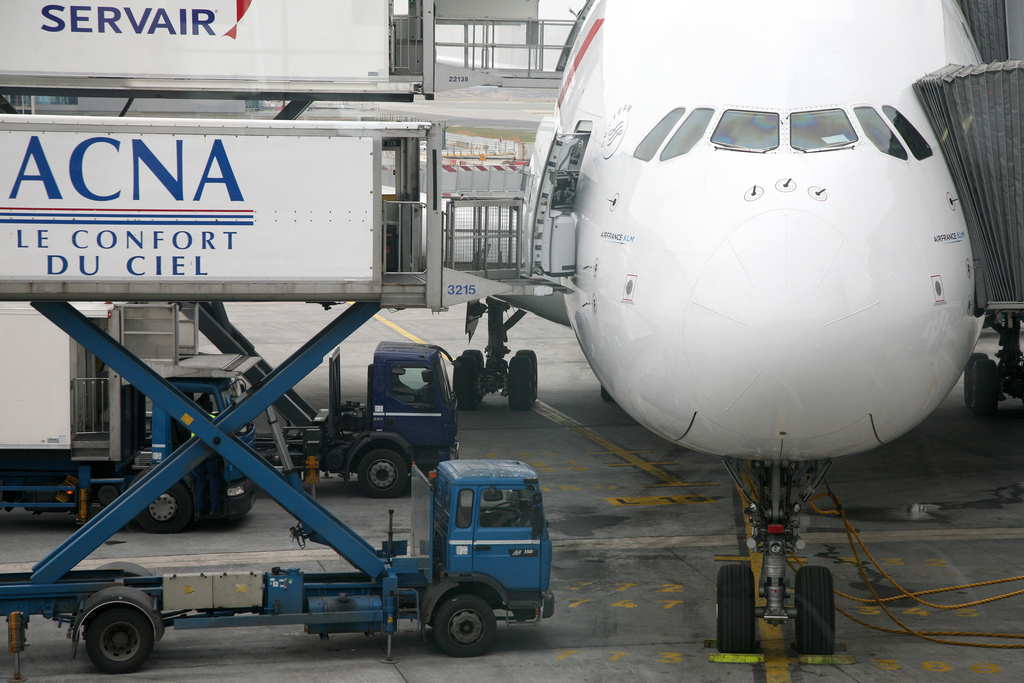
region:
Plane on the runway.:
[451, 51, 996, 618]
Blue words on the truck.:
[6, 111, 319, 293]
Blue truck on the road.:
[288, 441, 807, 638]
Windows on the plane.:
[615, 56, 971, 306]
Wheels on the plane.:
[688, 473, 905, 673]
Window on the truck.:
[452, 465, 555, 580]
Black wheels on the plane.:
[625, 444, 981, 647]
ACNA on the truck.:
[3, 125, 327, 252]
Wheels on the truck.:
[81, 548, 231, 678]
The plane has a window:
[714, 105, 781, 156]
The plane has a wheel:
[795, 566, 840, 661]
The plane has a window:
[847, 105, 931, 160]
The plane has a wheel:
[716, 557, 756, 656]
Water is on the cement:
[568, 522, 932, 656]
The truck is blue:
[19, 451, 548, 642]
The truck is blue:
[144, 342, 457, 507]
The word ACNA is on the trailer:
[6, 136, 253, 207]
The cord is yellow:
[821, 478, 1008, 644]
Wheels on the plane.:
[667, 529, 781, 657]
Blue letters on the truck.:
[27, 121, 291, 276]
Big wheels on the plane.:
[427, 302, 592, 427]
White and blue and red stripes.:
[550, 26, 643, 113]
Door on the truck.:
[417, 479, 522, 615]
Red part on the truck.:
[205, 10, 301, 71]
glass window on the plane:
[629, 108, 684, 159]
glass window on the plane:
[646, 100, 717, 159]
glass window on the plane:
[706, 103, 779, 154]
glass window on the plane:
[782, 100, 856, 154]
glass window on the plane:
[848, 104, 912, 163]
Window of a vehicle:
[479, 481, 534, 532]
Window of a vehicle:
[392, 363, 438, 406]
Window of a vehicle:
[386, 364, 434, 402]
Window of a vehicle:
[455, 489, 474, 528]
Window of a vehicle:
[480, 486, 532, 529]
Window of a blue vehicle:
[479, 483, 530, 531]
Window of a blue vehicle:
[457, 481, 478, 530]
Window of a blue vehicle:
[480, 487, 532, 532]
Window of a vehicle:
[389, 358, 434, 400]